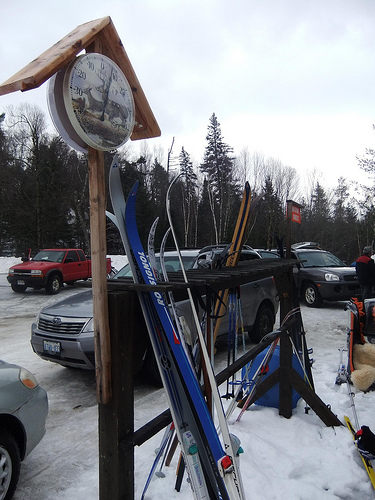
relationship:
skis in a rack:
[105, 155, 255, 499] [105, 255, 345, 498]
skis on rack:
[105, 155, 255, 499] [105, 255, 345, 498]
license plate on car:
[43, 339, 64, 353] [30, 243, 282, 388]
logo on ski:
[137, 251, 169, 315] [124, 178, 224, 465]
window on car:
[64, 251, 78, 264] [9, 247, 113, 294]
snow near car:
[120, 349, 374, 499] [30, 243, 282, 388]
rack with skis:
[105, 255, 345, 498] [105, 155, 255, 499]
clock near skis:
[48, 51, 136, 153] [105, 155, 255, 499]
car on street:
[30, 243, 282, 388] [105, 255, 345, 498]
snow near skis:
[120, 349, 374, 499] [105, 155, 255, 499]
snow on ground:
[120, 349, 374, 499] [105, 255, 345, 498]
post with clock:
[85, 153, 117, 407] [48, 51, 136, 153]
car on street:
[9, 247, 113, 294] [2, 271, 110, 481]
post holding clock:
[85, 153, 117, 407] [48, 51, 136, 153]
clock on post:
[48, 51, 136, 153] [85, 153, 117, 407]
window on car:
[64, 251, 78, 264] [30, 243, 282, 388]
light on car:
[30, 271, 42, 277] [9, 247, 113, 294]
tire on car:
[46, 274, 65, 294] [9, 247, 113, 294]